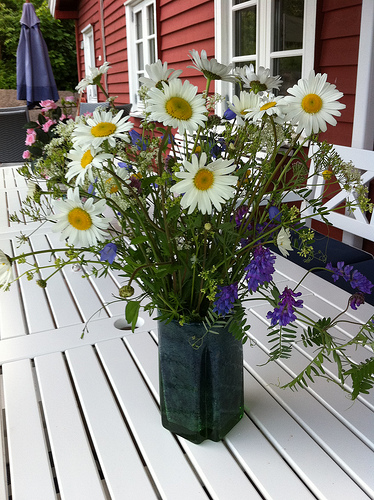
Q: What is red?
A: House.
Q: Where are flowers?
A: In a vase.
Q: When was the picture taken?
A: Daytime.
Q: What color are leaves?
A: Green.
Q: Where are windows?
A: On a house.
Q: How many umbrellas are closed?
A: One.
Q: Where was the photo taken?
A: On a deck.